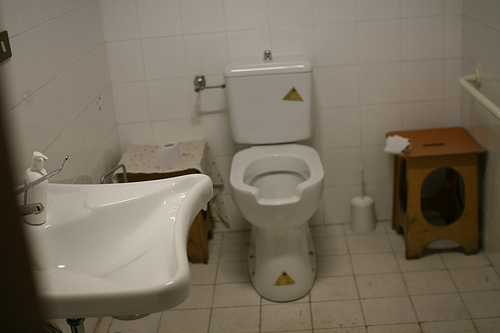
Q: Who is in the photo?
A: There is no one.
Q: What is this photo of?
A: A bathroom.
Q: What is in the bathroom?
A: A toilet.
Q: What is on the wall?
A: A sink.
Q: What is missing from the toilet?
A: A toilet seat.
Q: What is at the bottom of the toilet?
A: A caution sticker.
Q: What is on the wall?
A: White tile.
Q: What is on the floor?
A: White tile.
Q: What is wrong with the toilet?
A: No seat or lid.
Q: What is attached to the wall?
A: Sink.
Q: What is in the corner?
A: Wooden stool.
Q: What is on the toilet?
A: Stickers.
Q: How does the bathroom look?
A: Dirty.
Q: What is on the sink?
A: Hand soap.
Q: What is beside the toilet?
A: Toilet bowl cleaner.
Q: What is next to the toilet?
A: A stool.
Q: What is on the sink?
A: Hand soap.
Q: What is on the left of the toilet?
A: Toilet paper.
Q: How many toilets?
A: One.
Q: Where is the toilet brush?
A: On the floors.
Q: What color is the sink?
A: White.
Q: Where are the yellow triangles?
A: The toilet.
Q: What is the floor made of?
A: Tile.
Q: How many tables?
A: Two.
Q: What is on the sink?
A: A bottle.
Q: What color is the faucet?
A: Silver.